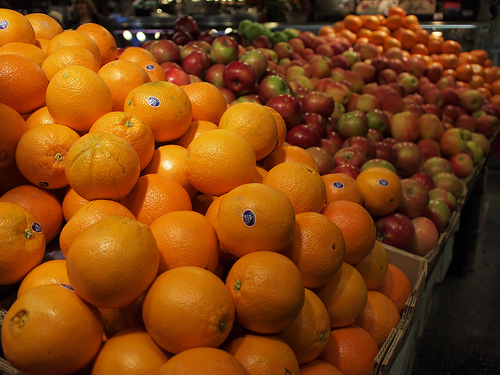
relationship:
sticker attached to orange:
[243, 207, 255, 227] [218, 186, 293, 255]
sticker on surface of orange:
[243, 207, 255, 227] [218, 186, 293, 255]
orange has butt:
[65, 128, 141, 204] [79, 138, 117, 170]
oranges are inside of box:
[2, 7, 407, 375] [373, 254, 433, 368]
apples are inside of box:
[141, 24, 472, 251] [427, 193, 468, 310]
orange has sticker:
[218, 186, 293, 255] [243, 207, 255, 227]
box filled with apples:
[427, 193, 468, 310] [141, 24, 472, 251]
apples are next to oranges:
[141, 24, 472, 251] [2, 7, 407, 375]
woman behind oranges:
[71, 1, 101, 26] [2, 7, 407, 375]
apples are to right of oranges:
[141, 24, 472, 251] [2, 7, 407, 375]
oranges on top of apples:
[322, 167, 405, 216] [141, 24, 472, 251]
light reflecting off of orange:
[430, 20, 447, 40] [428, 31, 442, 53]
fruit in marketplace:
[5, 3, 496, 360] [3, 1, 480, 372]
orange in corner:
[2, 289, 105, 373] [0, 293, 110, 373]